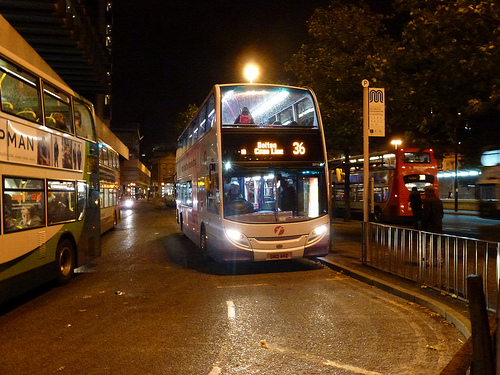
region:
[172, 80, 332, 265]
white double decker bus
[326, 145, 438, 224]
red double decker bus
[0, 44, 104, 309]
green and white bus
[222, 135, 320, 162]
number and destination of the white bus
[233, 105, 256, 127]
someone standing on the top floor of the white bus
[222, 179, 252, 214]
driver of the white bus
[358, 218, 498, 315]
metal railing by the curb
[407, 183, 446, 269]
two people walking on the sidewalk by the railing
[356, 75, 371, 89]
a small round sign with a P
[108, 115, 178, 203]
buildings in the background behind the buses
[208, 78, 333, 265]
the front of a double decked bus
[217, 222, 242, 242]
the headlight of a bus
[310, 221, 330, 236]
the headlight of a bus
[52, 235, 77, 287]
the wheel of a bus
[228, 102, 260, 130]
a person standing on the top deck of a bus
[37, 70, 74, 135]
a window in a bus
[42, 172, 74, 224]
a window in a bus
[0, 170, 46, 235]
a window in a bus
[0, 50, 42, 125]
a window in a bus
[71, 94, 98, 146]
a window in a bus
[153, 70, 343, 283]
a double decker bus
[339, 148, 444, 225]
the bus is red in color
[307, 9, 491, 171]
the tree is in the background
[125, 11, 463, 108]
the sky is dark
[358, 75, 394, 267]
a road sign is to the right of the bus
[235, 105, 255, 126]
a person is on the upper half of the bus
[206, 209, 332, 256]
the buses headlights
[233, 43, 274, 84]
a street light is behind the bus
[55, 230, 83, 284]
one of the buses tires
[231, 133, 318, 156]
the buses next destination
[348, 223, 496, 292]
Silver railing beside the bus.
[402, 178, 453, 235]
People walking on the street.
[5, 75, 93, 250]
Green bus filled with passengers.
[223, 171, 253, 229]
Bus driver waiting for passengers.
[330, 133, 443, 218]
Red bus on the other side of the street..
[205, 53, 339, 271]
Double decker white bus.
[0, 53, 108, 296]
Double decker green bus.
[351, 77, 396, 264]
Street sign hanging from a pole.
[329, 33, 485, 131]
Leafy green trees on the sidewalk.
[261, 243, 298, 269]
License plate on the bus.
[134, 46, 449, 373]
bus on the road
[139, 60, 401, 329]
white bus on the road